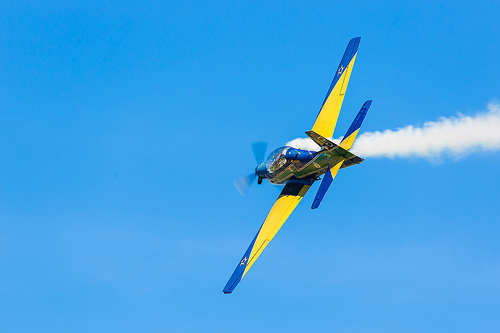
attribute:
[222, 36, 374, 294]
plane — yellow, blue, small, sky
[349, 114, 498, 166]
smoke trail — white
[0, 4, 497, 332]
sky — blue, nice, clear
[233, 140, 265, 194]
propeller — blue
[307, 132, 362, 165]
tail — yellow, blue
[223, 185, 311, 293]
wing — yellow, blue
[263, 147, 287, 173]
windshield — small